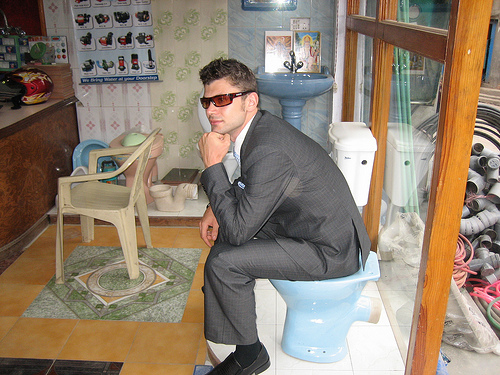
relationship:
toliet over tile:
[266, 250, 381, 365] [210, 274, 402, 374]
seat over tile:
[265, 249, 384, 365] [348, 344, 400, 374]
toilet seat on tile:
[269, 249, 380, 303] [0, 217, 402, 374]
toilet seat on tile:
[108, 132, 173, 163] [346, 322, 404, 371]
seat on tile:
[258, 249, 385, 372] [353, 331, 405, 373]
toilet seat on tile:
[269, 249, 380, 303] [275, 320, 355, 372]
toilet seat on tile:
[279, 263, 379, 302] [349, 325, 386, 373]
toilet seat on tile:
[269, 249, 380, 303] [205, 280, 405, 372]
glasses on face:
[198, 89, 257, 109] [198, 73, 264, 135]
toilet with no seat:
[259, 257, 381, 368] [262, 243, 386, 363]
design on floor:
[21, 245, 203, 322] [1, 188, 498, 371]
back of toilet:
[313, 120, 378, 212] [240, 116, 387, 369]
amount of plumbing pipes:
[418, 141, 498, 295] [458, 140, 499, 320]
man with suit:
[193, 58, 371, 375] [195, 106, 376, 349]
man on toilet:
[193, 56, 375, 373] [267, 243, 384, 366]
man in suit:
[193, 58, 371, 375] [195, 106, 376, 349]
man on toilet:
[193, 58, 371, 375] [236, 98, 373, 370]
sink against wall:
[251, 64, 338, 134] [207, 0, 408, 196]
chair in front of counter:
[55, 127, 159, 286] [3, 94, 80, 266]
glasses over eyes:
[198, 89, 257, 109] [200, 92, 230, 106]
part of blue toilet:
[357, 292, 384, 328] [267, 276, 380, 362]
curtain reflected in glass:
[391, 5, 417, 219] [351, 2, 457, 368]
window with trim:
[329, 0, 492, 363] [418, 142, 476, 307]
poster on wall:
[68, 1, 158, 85] [42, 0, 227, 187]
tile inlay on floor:
[25, 237, 202, 327] [4, 216, 226, 372]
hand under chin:
[188, 125, 237, 158] [210, 119, 226, 133]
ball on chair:
[120, 133, 147, 147] [40, 95, 185, 283]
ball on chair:
[120, 133, 147, 147] [92, 130, 162, 191]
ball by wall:
[115, 126, 156, 155] [62, 12, 200, 173]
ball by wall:
[120, 133, 147, 147] [75, 6, 205, 169]